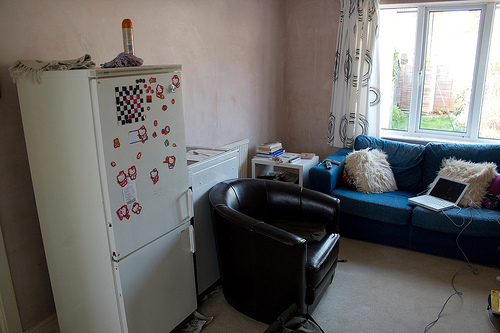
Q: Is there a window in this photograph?
A: Yes, there is a window.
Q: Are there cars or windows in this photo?
A: Yes, there is a window.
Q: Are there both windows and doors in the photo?
A: No, there is a window but no doors.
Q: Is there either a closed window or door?
A: Yes, there is a closed window.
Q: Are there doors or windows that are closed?
A: Yes, the window is closed.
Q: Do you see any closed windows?
A: Yes, there is a closed window.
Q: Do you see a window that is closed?
A: Yes, there is a window that is closed.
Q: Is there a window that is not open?
A: Yes, there is an closed window.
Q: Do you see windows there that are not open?
A: Yes, there is an closed window.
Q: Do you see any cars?
A: No, there are no cars.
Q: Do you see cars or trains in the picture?
A: No, there are no cars or trains.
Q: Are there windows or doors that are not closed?
A: No, there is a window but it is closed.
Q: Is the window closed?
A: Yes, the window is closed.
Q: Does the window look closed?
A: Yes, the window is closed.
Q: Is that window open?
A: No, the window is closed.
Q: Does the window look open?
A: No, the window is closed.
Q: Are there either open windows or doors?
A: No, there is a window but it is closed.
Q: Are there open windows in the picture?
A: No, there is a window but it is closed.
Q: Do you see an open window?
A: No, there is a window but it is closed.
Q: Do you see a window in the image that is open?
A: No, there is a window but it is closed.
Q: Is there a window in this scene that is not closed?
A: No, there is a window but it is closed.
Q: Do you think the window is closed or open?
A: The window is closed.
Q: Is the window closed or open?
A: The window is closed.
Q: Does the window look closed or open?
A: The window is closed.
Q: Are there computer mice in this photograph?
A: No, there are no computer mice.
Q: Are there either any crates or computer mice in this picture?
A: No, there are no computer mice or crates.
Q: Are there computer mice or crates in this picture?
A: No, there are no computer mice or crates.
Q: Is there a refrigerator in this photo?
A: Yes, there is a refrigerator.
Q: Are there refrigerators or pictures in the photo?
A: Yes, there is a refrigerator.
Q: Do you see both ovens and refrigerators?
A: No, there is a refrigerator but no ovens.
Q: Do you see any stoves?
A: No, there are no stoves.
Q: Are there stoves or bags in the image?
A: No, there are no stoves or bags.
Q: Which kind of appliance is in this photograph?
A: The appliance is a refrigerator.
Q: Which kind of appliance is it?
A: The appliance is a refrigerator.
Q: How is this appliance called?
A: This is a refrigerator.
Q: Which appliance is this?
A: This is a refrigerator.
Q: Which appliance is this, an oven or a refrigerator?
A: This is a refrigerator.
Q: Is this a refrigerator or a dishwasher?
A: This is a refrigerator.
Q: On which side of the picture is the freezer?
A: The freezer is on the left of the image.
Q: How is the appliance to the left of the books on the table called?
A: The appliance is a refrigerator.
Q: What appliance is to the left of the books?
A: The appliance is a refrigerator.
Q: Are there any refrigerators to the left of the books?
A: Yes, there is a refrigerator to the left of the books.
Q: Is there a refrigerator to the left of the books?
A: Yes, there is a refrigerator to the left of the books.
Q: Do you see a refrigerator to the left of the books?
A: Yes, there is a refrigerator to the left of the books.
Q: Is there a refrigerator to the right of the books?
A: No, the refrigerator is to the left of the books.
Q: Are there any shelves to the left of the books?
A: No, there is a refrigerator to the left of the books.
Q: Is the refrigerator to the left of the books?
A: Yes, the refrigerator is to the left of the books.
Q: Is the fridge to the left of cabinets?
A: No, the fridge is to the left of the books.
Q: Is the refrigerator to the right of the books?
A: No, the refrigerator is to the left of the books.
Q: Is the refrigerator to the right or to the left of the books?
A: The refrigerator is to the left of the books.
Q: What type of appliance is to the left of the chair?
A: The appliance is a refrigerator.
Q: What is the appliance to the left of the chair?
A: The appliance is a refrigerator.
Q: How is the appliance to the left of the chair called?
A: The appliance is a refrigerator.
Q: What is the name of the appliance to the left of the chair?
A: The appliance is a refrigerator.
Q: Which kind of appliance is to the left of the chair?
A: The appliance is a refrigerator.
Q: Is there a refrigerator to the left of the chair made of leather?
A: Yes, there is a refrigerator to the left of the chair.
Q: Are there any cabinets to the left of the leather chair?
A: No, there is a refrigerator to the left of the chair.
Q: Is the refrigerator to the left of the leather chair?
A: Yes, the refrigerator is to the left of the chair.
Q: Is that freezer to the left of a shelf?
A: No, the freezer is to the left of the chair.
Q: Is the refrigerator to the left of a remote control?
A: Yes, the refrigerator is to the left of a remote control.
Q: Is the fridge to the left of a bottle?
A: No, the fridge is to the left of a remote control.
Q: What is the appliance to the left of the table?
A: The appliance is a refrigerator.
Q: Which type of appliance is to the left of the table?
A: The appliance is a refrigerator.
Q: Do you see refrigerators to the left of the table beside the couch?
A: Yes, there is a refrigerator to the left of the table.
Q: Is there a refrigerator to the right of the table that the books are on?
A: No, the refrigerator is to the left of the table.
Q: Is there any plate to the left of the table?
A: No, there is a refrigerator to the left of the table.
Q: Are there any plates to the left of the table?
A: No, there is a refrigerator to the left of the table.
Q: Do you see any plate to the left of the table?
A: No, there is a refrigerator to the left of the table.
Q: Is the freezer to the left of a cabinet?
A: No, the freezer is to the left of a table.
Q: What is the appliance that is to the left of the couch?
A: The appliance is a refrigerator.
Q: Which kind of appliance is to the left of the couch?
A: The appliance is a refrigerator.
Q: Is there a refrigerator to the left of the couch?
A: Yes, there is a refrigerator to the left of the couch.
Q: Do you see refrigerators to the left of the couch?
A: Yes, there is a refrigerator to the left of the couch.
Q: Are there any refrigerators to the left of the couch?
A: Yes, there is a refrigerator to the left of the couch.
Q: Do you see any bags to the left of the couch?
A: No, there is a refrigerator to the left of the couch.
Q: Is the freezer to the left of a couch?
A: Yes, the freezer is to the left of a couch.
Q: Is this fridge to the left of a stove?
A: No, the fridge is to the left of a couch.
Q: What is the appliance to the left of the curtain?
A: The appliance is a refrigerator.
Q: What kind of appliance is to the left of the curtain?
A: The appliance is a refrigerator.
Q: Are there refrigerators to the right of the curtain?
A: No, the refrigerator is to the left of the curtain.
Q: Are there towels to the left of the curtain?
A: No, there is a refrigerator to the left of the curtain.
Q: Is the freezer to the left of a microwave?
A: No, the freezer is to the left of the curtain.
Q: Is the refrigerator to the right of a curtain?
A: No, the refrigerator is to the left of a curtain.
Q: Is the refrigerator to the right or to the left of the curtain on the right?
A: The refrigerator is to the left of the curtain.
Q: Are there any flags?
A: No, there are no flags.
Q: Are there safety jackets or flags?
A: No, there are no flags or safety jackets.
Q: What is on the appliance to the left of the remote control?
A: The magnet is on the refrigerator.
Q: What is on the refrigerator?
A: The magnet is on the refrigerator.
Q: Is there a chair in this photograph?
A: Yes, there is a chair.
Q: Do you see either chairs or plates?
A: Yes, there is a chair.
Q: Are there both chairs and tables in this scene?
A: Yes, there are both a chair and a table.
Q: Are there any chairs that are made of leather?
A: Yes, there is a chair that is made of leather.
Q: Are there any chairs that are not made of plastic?
A: Yes, there is a chair that is made of leather.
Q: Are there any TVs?
A: No, there are no tvs.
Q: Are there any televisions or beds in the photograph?
A: No, there are no televisions or beds.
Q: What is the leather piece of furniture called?
A: The piece of furniture is a chair.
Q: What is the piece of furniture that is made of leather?
A: The piece of furniture is a chair.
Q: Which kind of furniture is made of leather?
A: The furniture is a chair.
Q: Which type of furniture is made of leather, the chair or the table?
A: The chair is made of leather.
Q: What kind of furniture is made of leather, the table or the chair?
A: The chair is made of leather.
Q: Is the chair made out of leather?
A: Yes, the chair is made of leather.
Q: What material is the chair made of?
A: The chair is made of leather.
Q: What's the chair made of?
A: The chair is made of leather.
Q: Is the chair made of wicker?
A: No, the chair is made of leather.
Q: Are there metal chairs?
A: No, there is a chair but it is made of leather.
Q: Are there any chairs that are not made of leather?
A: No, there is a chair but it is made of leather.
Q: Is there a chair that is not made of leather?
A: No, there is a chair but it is made of leather.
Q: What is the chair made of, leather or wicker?
A: The chair is made of leather.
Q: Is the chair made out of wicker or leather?
A: The chair is made of leather.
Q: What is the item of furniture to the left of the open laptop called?
A: The piece of furniture is a chair.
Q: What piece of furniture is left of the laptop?
A: The piece of furniture is a chair.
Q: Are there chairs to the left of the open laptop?
A: Yes, there is a chair to the left of the laptop.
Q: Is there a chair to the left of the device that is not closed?
A: Yes, there is a chair to the left of the laptop.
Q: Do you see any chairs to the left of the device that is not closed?
A: Yes, there is a chair to the left of the laptop.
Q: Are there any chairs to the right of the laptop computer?
A: No, the chair is to the left of the laptop computer.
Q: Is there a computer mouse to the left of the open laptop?
A: No, there is a chair to the left of the laptop.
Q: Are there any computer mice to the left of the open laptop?
A: No, there is a chair to the left of the laptop.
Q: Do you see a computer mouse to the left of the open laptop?
A: No, there is a chair to the left of the laptop.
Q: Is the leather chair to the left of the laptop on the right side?
A: Yes, the chair is to the left of the laptop.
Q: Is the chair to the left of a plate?
A: No, the chair is to the left of the laptop.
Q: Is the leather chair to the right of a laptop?
A: No, the chair is to the left of a laptop.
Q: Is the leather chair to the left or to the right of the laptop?
A: The chair is to the left of the laptop.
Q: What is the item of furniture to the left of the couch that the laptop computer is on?
A: The piece of furniture is a chair.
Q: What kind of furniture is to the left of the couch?
A: The piece of furniture is a chair.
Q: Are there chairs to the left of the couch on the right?
A: Yes, there is a chair to the left of the couch.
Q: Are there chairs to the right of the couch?
A: No, the chair is to the left of the couch.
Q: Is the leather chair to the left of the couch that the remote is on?
A: Yes, the chair is to the left of the couch.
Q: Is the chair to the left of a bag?
A: No, the chair is to the left of the couch.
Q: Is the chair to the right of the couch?
A: No, the chair is to the left of the couch.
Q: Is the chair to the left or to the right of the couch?
A: The chair is to the left of the couch.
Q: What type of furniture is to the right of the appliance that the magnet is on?
A: The piece of furniture is a chair.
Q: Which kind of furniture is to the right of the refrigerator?
A: The piece of furniture is a chair.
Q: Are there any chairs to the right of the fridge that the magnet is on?
A: Yes, there is a chair to the right of the fridge.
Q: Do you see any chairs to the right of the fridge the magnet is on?
A: Yes, there is a chair to the right of the fridge.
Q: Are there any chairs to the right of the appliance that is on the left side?
A: Yes, there is a chair to the right of the fridge.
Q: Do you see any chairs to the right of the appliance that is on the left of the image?
A: Yes, there is a chair to the right of the fridge.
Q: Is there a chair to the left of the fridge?
A: No, the chair is to the right of the fridge.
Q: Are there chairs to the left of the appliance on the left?
A: No, the chair is to the right of the fridge.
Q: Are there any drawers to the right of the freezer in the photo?
A: No, there is a chair to the right of the freezer.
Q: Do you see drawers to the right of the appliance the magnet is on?
A: No, there is a chair to the right of the freezer.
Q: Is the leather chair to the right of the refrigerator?
A: Yes, the chair is to the right of the refrigerator.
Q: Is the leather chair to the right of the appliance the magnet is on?
A: Yes, the chair is to the right of the refrigerator.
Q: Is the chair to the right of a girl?
A: No, the chair is to the right of the refrigerator.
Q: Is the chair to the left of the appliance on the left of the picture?
A: No, the chair is to the right of the fridge.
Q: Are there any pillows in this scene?
A: Yes, there is a pillow.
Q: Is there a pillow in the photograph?
A: Yes, there is a pillow.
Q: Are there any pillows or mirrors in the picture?
A: Yes, there is a pillow.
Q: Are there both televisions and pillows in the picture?
A: No, there is a pillow but no televisions.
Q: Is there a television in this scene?
A: No, there are no televisions.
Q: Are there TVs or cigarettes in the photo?
A: No, there are no TVs or cigarettes.